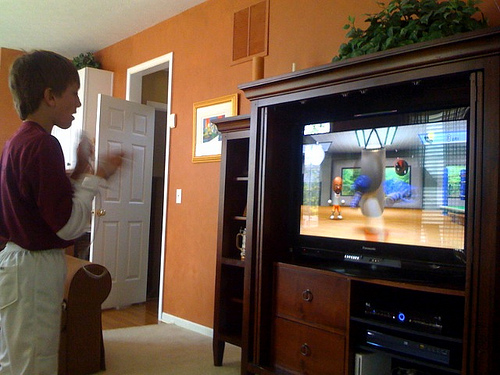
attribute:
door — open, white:
[87, 94, 156, 309]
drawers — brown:
[267, 263, 351, 374]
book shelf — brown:
[210, 115, 249, 365]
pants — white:
[0, 241, 65, 372]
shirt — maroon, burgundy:
[0, 122, 72, 250]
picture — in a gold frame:
[191, 92, 239, 163]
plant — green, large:
[326, 1, 492, 64]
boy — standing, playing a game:
[1, 50, 125, 374]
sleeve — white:
[58, 170, 105, 243]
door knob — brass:
[97, 209, 106, 218]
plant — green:
[73, 53, 102, 72]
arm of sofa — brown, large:
[63, 256, 111, 308]